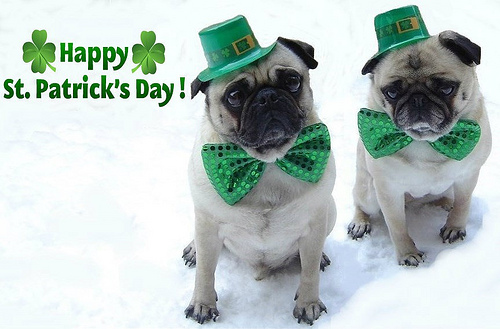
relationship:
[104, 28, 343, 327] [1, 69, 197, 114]
advertisement for st. patrick's day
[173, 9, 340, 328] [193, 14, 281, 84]
dog in hats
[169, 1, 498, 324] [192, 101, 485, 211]
two dogs wear bowties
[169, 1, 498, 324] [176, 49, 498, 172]
two dogs look uninterested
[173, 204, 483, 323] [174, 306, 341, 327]
paws have nails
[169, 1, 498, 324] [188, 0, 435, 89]
two dogs wear hats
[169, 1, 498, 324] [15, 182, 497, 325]
two dogs are in snow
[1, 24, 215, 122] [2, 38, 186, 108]
writing says happy st. patricks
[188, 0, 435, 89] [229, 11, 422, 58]
hats have gold buckles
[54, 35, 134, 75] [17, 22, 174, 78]
happy in between two four leaf clover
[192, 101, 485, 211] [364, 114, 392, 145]
bowties have sequins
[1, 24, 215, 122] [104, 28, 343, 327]
writing for advertisement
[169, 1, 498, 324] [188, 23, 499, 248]
two dogs are next to eachother